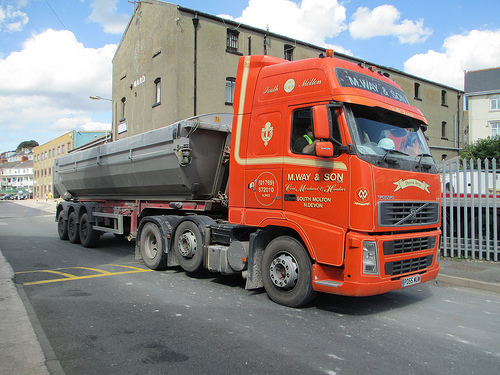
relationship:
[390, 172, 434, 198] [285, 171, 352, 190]
logo for trucking company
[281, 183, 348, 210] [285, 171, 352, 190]
location text for trucking company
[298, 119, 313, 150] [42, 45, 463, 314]
people in truck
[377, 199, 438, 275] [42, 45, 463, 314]
grilles on truck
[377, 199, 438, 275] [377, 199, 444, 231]
grilles for ventilation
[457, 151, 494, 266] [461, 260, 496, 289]
fence on sidewalk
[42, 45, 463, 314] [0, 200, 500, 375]
truck on road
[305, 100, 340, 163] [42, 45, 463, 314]
mirror on truck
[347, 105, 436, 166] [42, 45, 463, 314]
windshield on truck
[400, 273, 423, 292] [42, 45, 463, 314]
license plate on truck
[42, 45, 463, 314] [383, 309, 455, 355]
truck on road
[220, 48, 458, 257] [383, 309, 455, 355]
cab on road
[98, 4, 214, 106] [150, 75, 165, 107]
building with windows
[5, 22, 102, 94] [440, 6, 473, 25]
clouds in sky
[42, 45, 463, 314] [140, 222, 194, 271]
truck with lot of tires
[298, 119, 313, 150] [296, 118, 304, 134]
man in passenger seat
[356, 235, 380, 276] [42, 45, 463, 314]
headlight of truck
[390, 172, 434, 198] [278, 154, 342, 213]
logo on door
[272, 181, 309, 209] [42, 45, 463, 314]
door handle on truck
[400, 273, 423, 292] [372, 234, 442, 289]
license plate in front